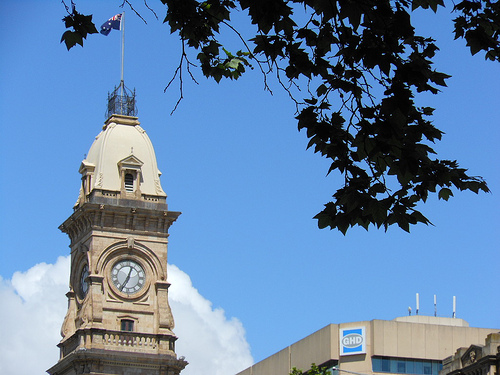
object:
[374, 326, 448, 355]
wall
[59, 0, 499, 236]
leaves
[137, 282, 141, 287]
roman numerals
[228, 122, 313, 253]
sky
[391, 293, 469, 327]
radio antanas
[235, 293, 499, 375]
building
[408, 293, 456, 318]
antenna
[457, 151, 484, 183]
ground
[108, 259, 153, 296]
bus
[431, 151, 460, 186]
ground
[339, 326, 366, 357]
sign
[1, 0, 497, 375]
blue sky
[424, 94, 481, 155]
sky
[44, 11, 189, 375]
building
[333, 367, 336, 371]
street light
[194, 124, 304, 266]
sky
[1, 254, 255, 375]
cloud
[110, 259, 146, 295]
clock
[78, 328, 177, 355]
balcony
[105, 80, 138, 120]
decoration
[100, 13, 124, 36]
flag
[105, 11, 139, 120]
top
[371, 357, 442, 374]
panes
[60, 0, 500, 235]
branches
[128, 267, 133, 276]
hand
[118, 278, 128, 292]
hand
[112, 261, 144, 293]
numerals